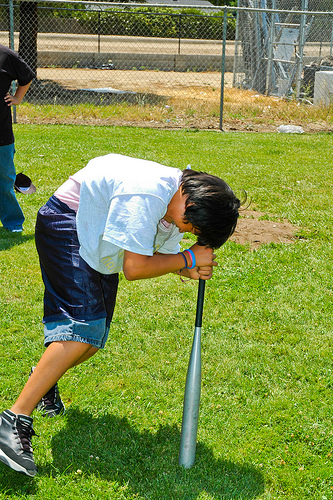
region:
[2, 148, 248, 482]
A boy holding a bat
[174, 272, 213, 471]
A silver metal bat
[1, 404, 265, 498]
Shadow on the grass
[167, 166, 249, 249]
Black hair on boy's head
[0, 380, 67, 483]
A pair of black sneakers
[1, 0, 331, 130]
A fence behind the boy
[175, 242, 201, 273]
Two bracelets around boy's wrist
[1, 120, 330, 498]
A field of green grass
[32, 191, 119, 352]
A pair of blue shorts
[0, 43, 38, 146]
Person wearing a black shirt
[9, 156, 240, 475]
kid spinning on a baseball bat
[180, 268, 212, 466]
aluminum baseball bat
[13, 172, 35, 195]
baseball cap on the ground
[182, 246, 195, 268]
blue and red wristbands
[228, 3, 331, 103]
storage area behind a fence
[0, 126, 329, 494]
green grass playing field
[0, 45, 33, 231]
person in black shirt and blue jeans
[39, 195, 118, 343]
blue shorts over blue jean shorts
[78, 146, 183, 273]
light gray t-shirt on kid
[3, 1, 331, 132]
chain link fence surrounding the playing field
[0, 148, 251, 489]
young boy spinning head on baseball bat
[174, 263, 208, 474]
silver and black baseball bat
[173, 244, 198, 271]
blue, pink, and black bracelets on a wrist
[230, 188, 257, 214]
wisp of black hair blowing in the wind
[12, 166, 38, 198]
black and brown hat on the ground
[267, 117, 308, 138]
small patch of snow melting near a fence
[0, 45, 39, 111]
right arm of person standing outside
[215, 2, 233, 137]
silver metal pole on a fence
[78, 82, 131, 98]
small patch of snow melting under a tree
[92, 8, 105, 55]
metal pole on a fence outside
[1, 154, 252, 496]
the boy is bent at the waist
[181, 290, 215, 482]
the bat is grey and black in colour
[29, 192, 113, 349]
he has a dark blue short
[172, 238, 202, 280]
he has bangles his hands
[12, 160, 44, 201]
the cap is on the grass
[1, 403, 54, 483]
his shoes are black in colour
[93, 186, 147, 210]
his shirt is white in colour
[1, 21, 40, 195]
the mans hands are on the waist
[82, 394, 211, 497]
the boys shadow is on the ground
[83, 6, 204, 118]
the fenceis made of a metal of wire mesh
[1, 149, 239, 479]
this kid looks pretty frustrated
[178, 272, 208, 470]
this kid is holding a baseball bat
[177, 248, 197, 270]
this kid is wearing several bracelets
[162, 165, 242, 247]
this kid has dark hair cut rather long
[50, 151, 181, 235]
this kid is wearing a pink undershirt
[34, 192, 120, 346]
this kid is wearing blue shorts with jeans-style accents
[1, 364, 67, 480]
this kid is not wearing socks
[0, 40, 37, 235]
this kid has a witness to his frustration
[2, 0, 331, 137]
a chain link fence borders this ball park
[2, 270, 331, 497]
the grass is very green here